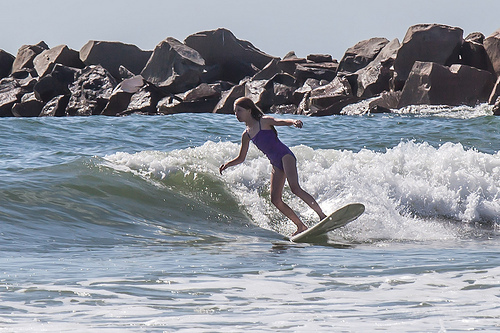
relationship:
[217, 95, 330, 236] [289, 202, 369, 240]
girl balancing on surfboard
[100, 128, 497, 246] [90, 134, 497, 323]
wave starting to break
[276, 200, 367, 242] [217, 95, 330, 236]
girl on girl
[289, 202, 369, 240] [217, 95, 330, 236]
surfboard surfing girl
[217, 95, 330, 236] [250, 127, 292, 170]
girl wearing swimsuit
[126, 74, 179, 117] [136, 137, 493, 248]
animal sitting on breakwater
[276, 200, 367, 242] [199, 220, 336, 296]
surf board in water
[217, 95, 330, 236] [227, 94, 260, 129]
girl on head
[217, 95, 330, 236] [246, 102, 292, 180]
girl on bathing suit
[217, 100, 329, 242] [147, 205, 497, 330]
girl surfing wave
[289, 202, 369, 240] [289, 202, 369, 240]
surfboard riding surfboard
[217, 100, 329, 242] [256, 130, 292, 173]
girl in bathing suit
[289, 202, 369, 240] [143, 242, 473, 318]
surfboard on ocean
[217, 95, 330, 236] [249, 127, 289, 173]
girl in swimsuit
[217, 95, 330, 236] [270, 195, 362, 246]
girl balancing on surfboard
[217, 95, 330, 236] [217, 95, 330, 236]
girl holding out girl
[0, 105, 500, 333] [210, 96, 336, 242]
water churning behind surfer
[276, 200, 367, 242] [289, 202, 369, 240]
surfer on surfboard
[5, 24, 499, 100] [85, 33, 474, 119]
row near boulders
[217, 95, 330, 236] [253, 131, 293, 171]
girl wearing swimsuit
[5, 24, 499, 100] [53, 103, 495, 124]
rocks on beach